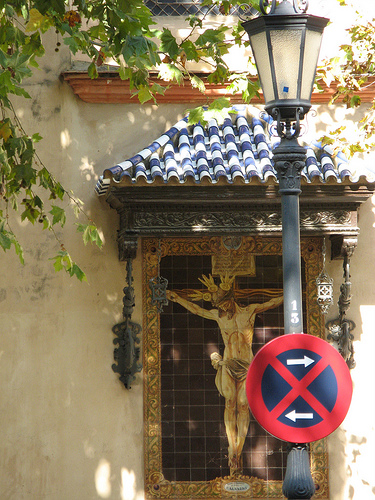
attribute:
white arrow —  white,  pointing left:
[283, 408, 313, 422]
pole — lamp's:
[265, 161, 328, 300]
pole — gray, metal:
[270, 179, 348, 479]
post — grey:
[272, 95, 313, 498]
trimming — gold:
[144, 236, 163, 499]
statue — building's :
[157, 270, 312, 481]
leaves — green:
[1, 0, 235, 93]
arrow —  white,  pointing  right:
[286, 353, 314, 368]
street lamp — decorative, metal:
[249, 6, 331, 498]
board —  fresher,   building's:
[63, 67, 255, 114]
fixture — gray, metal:
[114, 255, 147, 394]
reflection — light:
[309, 124, 315, 139]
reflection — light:
[335, 106, 344, 120]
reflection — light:
[120, 468, 136, 498]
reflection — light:
[355, 304, 371, 422]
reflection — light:
[95, 459, 111, 496]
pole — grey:
[277, 193, 310, 330]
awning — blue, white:
[94, 105, 372, 196]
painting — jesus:
[157, 248, 309, 415]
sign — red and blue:
[279, 351, 358, 463]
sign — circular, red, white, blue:
[246, 333, 352, 443]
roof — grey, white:
[92, 106, 374, 198]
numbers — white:
[288, 300, 300, 332]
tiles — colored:
[101, 119, 372, 182]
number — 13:
[289, 299, 298, 323]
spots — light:
[13, 98, 192, 318]